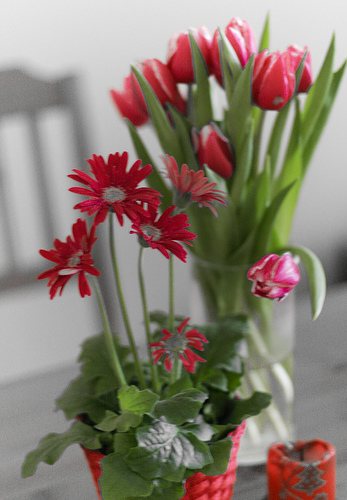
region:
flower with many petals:
[64, 142, 158, 249]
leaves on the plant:
[140, 391, 207, 465]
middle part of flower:
[99, 180, 127, 210]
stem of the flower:
[100, 230, 134, 295]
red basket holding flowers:
[210, 421, 255, 476]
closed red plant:
[246, 38, 302, 107]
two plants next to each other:
[67, 31, 307, 287]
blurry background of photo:
[8, 57, 94, 145]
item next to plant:
[267, 425, 332, 491]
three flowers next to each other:
[37, 165, 177, 290]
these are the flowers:
[109, 27, 334, 161]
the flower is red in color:
[260, 58, 293, 103]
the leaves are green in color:
[124, 393, 216, 479]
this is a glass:
[259, 299, 287, 403]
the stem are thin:
[103, 266, 164, 343]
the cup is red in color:
[206, 482, 224, 497]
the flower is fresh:
[251, 54, 290, 103]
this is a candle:
[297, 435, 332, 495]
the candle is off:
[265, 430, 338, 497]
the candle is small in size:
[266, 432, 333, 495]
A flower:
[78, 130, 215, 280]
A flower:
[83, 199, 190, 286]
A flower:
[103, 158, 172, 242]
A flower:
[173, 284, 223, 371]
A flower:
[150, 299, 225, 423]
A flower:
[150, 308, 202, 364]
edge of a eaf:
[115, 441, 146, 474]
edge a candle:
[292, 458, 317, 478]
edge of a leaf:
[159, 453, 192, 490]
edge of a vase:
[80, 442, 98, 468]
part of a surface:
[244, 469, 255, 484]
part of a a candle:
[279, 466, 287, 489]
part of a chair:
[251, 448, 258, 458]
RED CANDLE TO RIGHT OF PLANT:
[262, 439, 344, 497]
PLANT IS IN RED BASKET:
[67, 406, 237, 497]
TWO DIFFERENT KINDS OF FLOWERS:
[31, 26, 320, 389]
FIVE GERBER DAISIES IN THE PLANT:
[32, 153, 221, 369]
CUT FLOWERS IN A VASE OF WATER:
[161, 248, 294, 436]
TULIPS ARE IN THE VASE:
[111, 22, 297, 290]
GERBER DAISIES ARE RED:
[15, 168, 185, 256]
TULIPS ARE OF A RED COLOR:
[123, 9, 328, 113]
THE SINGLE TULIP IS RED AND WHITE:
[236, 237, 305, 298]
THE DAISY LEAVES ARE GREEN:
[70, 358, 226, 478]